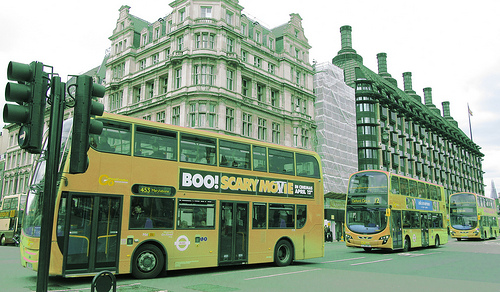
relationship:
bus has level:
[21, 112, 326, 278] [26, 114, 325, 188]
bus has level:
[21, 112, 326, 278] [16, 181, 325, 282]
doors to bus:
[69, 192, 121, 272] [21, 112, 326, 278]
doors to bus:
[216, 196, 251, 266] [21, 112, 326, 278]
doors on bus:
[199, 210, 250, 267] [21, 112, 326, 278]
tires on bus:
[130, 239, 304, 273] [21, 112, 326, 278]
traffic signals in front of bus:
[4, 55, 47, 154] [21, 112, 326, 278]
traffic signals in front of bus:
[68, 69, 106, 175] [21, 112, 326, 278]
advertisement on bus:
[168, 167, 318, 203] [14, 107, 332, 285]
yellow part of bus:
[103, 159, 143, 175] [21, 112, 326, 278]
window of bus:
[180, 132, 217, 164] [448, 191, 498, 239]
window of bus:
[135, 125, 177, 160] [343, 168, 446, 252]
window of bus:
[89, 117, 132, 154] [21, 112, 326, 278]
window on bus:
[181, 129, 218, 168] [21, 112, 326, 278]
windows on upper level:
[86, 116, 321, 178] [231, 51, 272, 120]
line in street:
[355, 255, 395, 264] [0, 237, 496, 290]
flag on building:
[452, 99, 488, 146] [320, 69, 485, 219]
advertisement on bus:
[155, 164, 315, 199] [332, 158, 469, 255]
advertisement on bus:
[155, 164, 315, 199] [21, 112, 326, 278]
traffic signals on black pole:
[1, 50, 174, 161] [8, 164, 113, 287]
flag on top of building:
[467, 105, 473, 117] [2, 1, 499, 248]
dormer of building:
[265, 7, 318, 126] [54, 10, 314, 257]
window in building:
[238, 72, 256, 102] [2, 1, 499, 248]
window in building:
[251, 75, 269, 106] [2, 1, 499, 248]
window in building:
[262, 82, 285, 112] [2, 1, 499, 248]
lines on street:
[224, 252, 454, 282] [3, 233, 498, 288]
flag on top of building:
[467, 105, 473, 117] [5, 15, 484, 224]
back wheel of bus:
[275, 240, 292, 266] [343, 168, 446, 252]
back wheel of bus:
[434, 234, 440, 246] [21, 112, 326, 278]